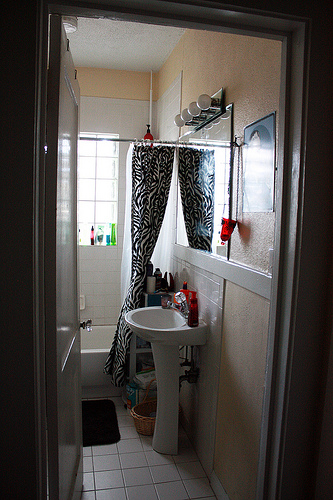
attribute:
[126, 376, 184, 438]
basket — brown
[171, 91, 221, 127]
globes — white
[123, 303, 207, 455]
sink — white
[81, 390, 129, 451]
rug — black